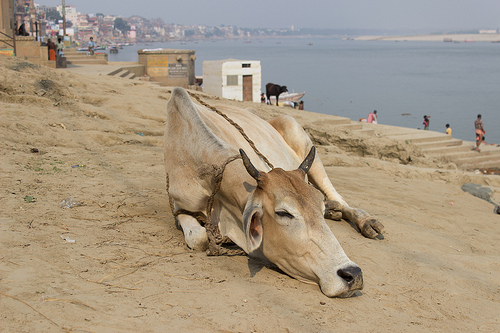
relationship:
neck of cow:
[204, 149, 250, 253] [96, 84, 391, 294]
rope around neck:
[204, 150, 244, 259] [204, 149, 250, 253]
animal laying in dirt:
[164, 85, 384, 299] [0, 51, 499, 331]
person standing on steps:
[474, 113, 486, 152] [374, 123, 499, 172]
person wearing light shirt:
[86, 36, 96, 55] [87, 42, 93, 49]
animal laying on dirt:
[164, 85, 384, 299] [40, 175, 137, 295]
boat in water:
[261, 90, 306, 106] [107, 32, 495, 119]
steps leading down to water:
[404, 129, 498, 171] [122, 41, 497, 158]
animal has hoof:
[164, 85, 384, 299] [362, 218, 384, 238]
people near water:
[354, 100, 488, 152] [197, 33, 497, 125]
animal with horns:
[164, 85, 384, 299] [235, 135, 325, 199]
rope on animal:
[174, 88, 274, 256] [164, 85, 384, 299]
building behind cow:
[202, 57, 262, 103] [155, 79, 394, 316]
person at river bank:
[470, 110, 486, 150] [112, 62, 499, 179]